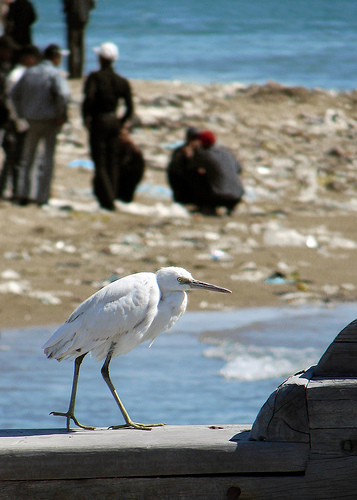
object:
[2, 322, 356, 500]
fence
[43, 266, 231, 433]
bird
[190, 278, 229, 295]
beak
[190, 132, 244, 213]
person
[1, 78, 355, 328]
beach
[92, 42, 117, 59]
cap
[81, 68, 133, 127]
shirt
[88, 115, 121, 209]
pants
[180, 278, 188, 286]
eye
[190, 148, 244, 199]
jacket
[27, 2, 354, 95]
water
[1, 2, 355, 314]
background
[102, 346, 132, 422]
leg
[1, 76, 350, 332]
ground